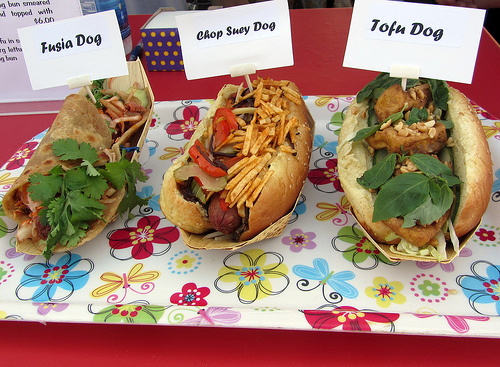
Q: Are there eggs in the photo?
A: No, there are no eggs.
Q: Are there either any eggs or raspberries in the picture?
A: No, there are no eggs or raspberries.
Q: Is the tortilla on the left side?
A: Yes, the tortilla is on the left of the image.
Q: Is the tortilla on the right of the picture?
A: No, the tortilla is on the left of the image.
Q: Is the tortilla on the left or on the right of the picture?
A: The tortilla is on the left of the image.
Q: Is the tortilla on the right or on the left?
A: The tortilla is on the left of the image.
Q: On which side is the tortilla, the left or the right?
A: The tortilla is on the left of the image.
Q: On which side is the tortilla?
A: The tortilla is on the left of the image.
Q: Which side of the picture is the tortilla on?
A: The tortilla is on the left of the image.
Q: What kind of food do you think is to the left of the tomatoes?
A: The food is a tortilla.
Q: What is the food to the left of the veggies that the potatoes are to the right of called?
A: The food is a tortilla.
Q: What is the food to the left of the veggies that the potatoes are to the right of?
A: The food is a tortilla.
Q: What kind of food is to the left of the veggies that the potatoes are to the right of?
A: The food is a tortilla.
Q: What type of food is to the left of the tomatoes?
A: The food is a tortilla.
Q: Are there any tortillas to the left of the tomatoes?
A: Yes, there is a tortilla to the left of the tomatoes.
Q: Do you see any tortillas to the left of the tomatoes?
A: Yes, there is a tortilla to the left of the tomatoes.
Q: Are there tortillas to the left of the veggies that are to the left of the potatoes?
A: Yes, there is a tortilla to the left of the tomatoes.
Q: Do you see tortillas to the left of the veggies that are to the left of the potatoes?
A: Yes, there is a tortilla to the left of the tomatoes.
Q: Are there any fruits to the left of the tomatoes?
A: No, there is a tortilla to the left of the tomatoes.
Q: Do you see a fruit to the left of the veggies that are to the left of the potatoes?
A: No, there is a tortilla to the left of the tomatoes.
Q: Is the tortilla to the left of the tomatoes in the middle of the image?
A: Yes, the tortilla is to the left of the tomatoes.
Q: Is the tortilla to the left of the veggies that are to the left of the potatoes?
A: Yes, the tortilla is to the left of the tomatoes.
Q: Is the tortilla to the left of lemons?
A: No, the tortilla is to the left of the tomatoes.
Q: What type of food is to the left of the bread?
A: The food is a tortilla.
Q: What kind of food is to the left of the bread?
A: The food is a tortilla.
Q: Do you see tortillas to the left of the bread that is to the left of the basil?
A: Yes, there is a tortilla to the left of the bread.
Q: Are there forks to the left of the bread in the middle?
A: No, there is a tortilla to the left of the bread.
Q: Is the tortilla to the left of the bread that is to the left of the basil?
A: Yes, the tortilla is to the left of the bread.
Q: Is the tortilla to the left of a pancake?
A: No, the tortilla is to the left of the bread.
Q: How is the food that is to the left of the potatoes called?
A: The food is a tortilla.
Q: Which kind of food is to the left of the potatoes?
A: The food is a tortilla.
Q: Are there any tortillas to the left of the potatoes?
A: Yes, there is a tortilla to the left of the potatoes.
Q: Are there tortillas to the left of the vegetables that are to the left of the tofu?
A: Yes, there is a tortilla to the left of the potatoes.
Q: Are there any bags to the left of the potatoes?
A: No, there is a tortilla to the left of the potatoes.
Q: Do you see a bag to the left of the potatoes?
A: No, there is a tortilla to the left of the potatoes.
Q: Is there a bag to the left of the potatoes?
A: No, there is a tortilla to the left of the potatoes.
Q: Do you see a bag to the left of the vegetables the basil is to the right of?
A: No, there is a tortilla to the left of the potatoes.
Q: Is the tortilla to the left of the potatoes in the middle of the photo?
A: Yes, the tortilla is to the left of the potatoes.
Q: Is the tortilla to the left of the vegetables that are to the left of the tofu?
A: Yes, the tortilla is to the left of the potatoes.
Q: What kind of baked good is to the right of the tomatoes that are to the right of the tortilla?
A: The food is a bun.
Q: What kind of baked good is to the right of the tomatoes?
A: The food is a bun.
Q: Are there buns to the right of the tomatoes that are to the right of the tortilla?
A: Yes, there is a bun to the right of the tomatoes.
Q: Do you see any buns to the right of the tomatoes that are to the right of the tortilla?
A: Yes, there is a bun to the right of the tomatoes.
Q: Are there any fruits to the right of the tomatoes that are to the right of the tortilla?
A: No, there is a bun to the right of the tomatoes.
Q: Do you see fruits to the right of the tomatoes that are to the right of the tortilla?
A: No, there is a bun to the right of the tomatoes.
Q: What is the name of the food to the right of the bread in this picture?
A: The food is a bun.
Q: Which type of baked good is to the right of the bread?
A: The food is a bun.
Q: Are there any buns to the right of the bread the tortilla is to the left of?
A: Yes, there is a bun to the right of the bread.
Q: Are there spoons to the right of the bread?
A: No, there is a bun to the right of the bread.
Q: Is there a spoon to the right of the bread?
A: No, there is a bun to the right of the bread.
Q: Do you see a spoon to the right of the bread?
A: No, there is a bun to the right of the bread.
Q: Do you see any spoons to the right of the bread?
A: No, there is a bun to the right of the bread.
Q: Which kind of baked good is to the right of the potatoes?
A: The food is a bun.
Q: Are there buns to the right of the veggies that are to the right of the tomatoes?
A: Yes, there is a bun to the right of the potatoes.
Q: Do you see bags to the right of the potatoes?
A: No, there is a bun to the right of the potatoes.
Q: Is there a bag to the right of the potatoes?
A: No, there is a bun to the right of the potatoes.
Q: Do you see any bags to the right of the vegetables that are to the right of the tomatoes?
A: No, there is a bun to the right of the potatoes.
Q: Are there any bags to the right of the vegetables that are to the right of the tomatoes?
A: No, there is a bun to the right of the potatoes.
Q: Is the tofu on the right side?
A: Yes, the tofu is on the right of the image.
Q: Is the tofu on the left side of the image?
A: No, the tofu is on the right of the image.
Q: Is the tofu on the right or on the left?
A: The tofu is on the right of the image.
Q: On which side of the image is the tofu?
A: The tofu is on the right of the image.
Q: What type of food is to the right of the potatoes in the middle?
A: The food is tofu.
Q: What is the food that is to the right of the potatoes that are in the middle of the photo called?
A: The food is tofu.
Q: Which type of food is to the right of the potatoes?
A: The food is tofu.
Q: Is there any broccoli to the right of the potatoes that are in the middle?
A: No, there is tofu to the right of the potatoes.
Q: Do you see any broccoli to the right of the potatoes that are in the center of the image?
A: No, there is tofu to the right of the potatoes.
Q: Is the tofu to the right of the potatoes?
A: Yes, the tofu is to the right of the potatoes.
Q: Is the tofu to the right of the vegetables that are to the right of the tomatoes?
A: Yes, the tofu is to the right of the potatoes.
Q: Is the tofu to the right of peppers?
A: No, the tofu is to the right of the potatoes.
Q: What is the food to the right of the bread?
A: The food is tofu.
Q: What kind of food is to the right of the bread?
A: The food is tofu.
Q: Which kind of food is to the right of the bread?
A: The food is tofu.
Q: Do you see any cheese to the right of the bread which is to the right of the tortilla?
A: No, there is tofu to the right of the bread.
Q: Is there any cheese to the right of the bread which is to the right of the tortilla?
A: No, there is tofu to the right of the bread.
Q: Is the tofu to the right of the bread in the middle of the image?
A: Yes, the tofu is to the right of the bread.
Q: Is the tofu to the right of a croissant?
A: No, the tofu is to the right of the bread.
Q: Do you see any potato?
A: Yes, there are potatoes.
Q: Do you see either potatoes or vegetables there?
A: Yes, there are potatoes.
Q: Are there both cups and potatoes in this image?
A: No, there are potatoes but no cups.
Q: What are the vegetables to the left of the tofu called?
A: The vegetables are potatoes.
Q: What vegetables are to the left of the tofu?
A: The vegetables are potatoes.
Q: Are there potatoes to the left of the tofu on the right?
A: Yes, there are potatoes to the left of the tofu.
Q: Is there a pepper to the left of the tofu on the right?
A: No, there are potatoes to the left of the tofu.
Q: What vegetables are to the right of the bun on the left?
A: The vegetables are potatoes.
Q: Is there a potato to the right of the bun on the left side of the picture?
A: Yes, there are potatoes to the right of the bun.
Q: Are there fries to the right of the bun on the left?
A: No, there are potatoes to the right of the bun.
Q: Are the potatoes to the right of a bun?
A: Yes, the potatoes are to the right of a bun.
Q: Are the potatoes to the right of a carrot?
A: No, the potatoes are to the right of a bun.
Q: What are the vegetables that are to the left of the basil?
A: The vegetables are potatoes.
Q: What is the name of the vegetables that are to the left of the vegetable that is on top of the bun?
A: The vegetables are potatoes.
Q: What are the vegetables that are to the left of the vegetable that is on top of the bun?
A: The vegetables are potatoes.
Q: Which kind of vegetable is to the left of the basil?
A: The vegetables are potatoes.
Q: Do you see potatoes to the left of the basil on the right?
A: Yes, there are potatoes to the left of the basil.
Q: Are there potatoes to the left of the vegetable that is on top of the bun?
A: Yes, there are potatoes to the left of the basil.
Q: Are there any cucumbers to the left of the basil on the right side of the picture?
A: No, there are potatoes to the left of the basil.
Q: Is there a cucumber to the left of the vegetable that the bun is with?
A: No, there are potatoes to the left of the basil.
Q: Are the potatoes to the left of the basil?
A: Yes, the potatoes are to the left of the basil.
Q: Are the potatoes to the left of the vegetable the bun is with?
A: Yes, the potatoes are to the left of the basil.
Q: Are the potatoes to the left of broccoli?
A: No, the potatoes are to the left of the basil.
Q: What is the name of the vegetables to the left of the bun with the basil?
A: The vegetables are potatoes.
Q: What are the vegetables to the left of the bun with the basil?
A: The vegetables are potatoes.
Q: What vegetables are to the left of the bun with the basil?
A: The vegetables are potatoes.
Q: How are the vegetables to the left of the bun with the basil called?
A: The vegetables are potatoes.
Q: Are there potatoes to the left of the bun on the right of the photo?
A: Yes, there are potatoes to the left of the bun.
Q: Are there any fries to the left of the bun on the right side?
A: No, there are potatoes to the left of the bun.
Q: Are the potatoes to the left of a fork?
A: No, the potatoes are to the left of the bun.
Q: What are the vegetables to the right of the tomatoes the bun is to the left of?
A: The vegetables are potatoes.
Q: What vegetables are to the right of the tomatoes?
A: The vegetables are potatoes.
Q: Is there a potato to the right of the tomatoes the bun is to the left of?
A: Yes, there are potatoes to the right of the tomatoes.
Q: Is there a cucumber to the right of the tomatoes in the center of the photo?
A: No, there are potatoes to the right of the tomatoes.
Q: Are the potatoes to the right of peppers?
A: No, the potatoes are to the right of the tomatoes.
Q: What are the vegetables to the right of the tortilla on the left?
A: The vegetables are potatoes.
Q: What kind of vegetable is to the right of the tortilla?
A: The vegetables are potatoes.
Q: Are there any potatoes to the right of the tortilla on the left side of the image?
A: Yes, there are potatoes to the right of the tortilla.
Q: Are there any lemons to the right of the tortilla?
A: No, there are potatoes to the right of the tortilla.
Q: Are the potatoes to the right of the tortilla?
A: Yes, the potatoes are to the right of the tortilla.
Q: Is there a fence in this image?
A: No, there are no fences.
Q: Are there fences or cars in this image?
A: No, there are no fences or cars.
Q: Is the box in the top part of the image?
A: Yes, the box is in the top of the image.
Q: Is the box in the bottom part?
A: No, the box is in the top of the image.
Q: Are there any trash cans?
A: No, there are no trash cans.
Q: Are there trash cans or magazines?
A: No, there are no trash cans or magazines.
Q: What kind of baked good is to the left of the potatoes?
A: The food is a bun.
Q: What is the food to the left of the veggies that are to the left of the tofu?
A: The food is a bun.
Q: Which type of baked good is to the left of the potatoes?
A: The food is a bun.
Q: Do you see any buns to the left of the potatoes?
A: Yes, there is a bun to the left of the potatoes.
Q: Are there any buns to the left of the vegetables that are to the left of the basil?
A: Yes, there is a bun to the left of the potatoes.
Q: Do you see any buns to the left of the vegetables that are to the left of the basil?
A: Yes, there is a bun to the left of the potatoes.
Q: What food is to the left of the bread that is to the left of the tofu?
A: The food is a bun.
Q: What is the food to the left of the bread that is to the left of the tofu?
A: The food is a bun.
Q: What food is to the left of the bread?
A: The food is a bun.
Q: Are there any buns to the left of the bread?
A: Yes, there is a bun to the left of the bread.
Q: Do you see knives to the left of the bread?
A: No, there is a bun to the left of the bread.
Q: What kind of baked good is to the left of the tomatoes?
A: The food is a bun.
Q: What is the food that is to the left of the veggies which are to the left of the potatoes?
A: The food is a bun.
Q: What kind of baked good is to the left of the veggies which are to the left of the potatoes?
A: The food is a bun.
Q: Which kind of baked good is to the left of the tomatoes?
A: The food is a bun.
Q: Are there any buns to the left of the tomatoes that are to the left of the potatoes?
A: Yes, there is a bun to the left of the tomatoes.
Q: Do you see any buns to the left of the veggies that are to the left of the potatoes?
A: Yes, there is a bun to the left of the tomatoes.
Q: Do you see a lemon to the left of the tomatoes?
A: No, there is a bun to the left of the tomatoes.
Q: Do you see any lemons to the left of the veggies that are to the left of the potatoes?
A: No, there is a bun to the left of the tomatoes.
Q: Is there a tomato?
A: Yes, there are tomatoes.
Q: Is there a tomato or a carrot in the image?
A: Yes, there are tomatoes.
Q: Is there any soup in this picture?
A: No, there is no soup.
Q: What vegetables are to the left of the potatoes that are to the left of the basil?
A: The vegetables are tomatoes.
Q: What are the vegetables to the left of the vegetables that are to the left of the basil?
A: The vegetables are tomatoes.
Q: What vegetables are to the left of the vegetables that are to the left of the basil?
A: The vegetables are tomatoes.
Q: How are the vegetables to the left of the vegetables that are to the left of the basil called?
A: The vegetables are tomatoes.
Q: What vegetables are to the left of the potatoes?
A: The vegetables are tomatoes.